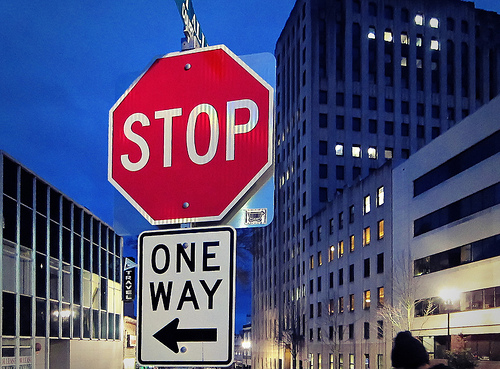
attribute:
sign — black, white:
[129, 220, 246, 360]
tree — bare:
[361, 255, 450, 338]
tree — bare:
[366, 240, 435, 366]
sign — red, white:
[109, 54, 276, 229]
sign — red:
[103, 48, 287, 228]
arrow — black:
[146, 315, 224, 359]